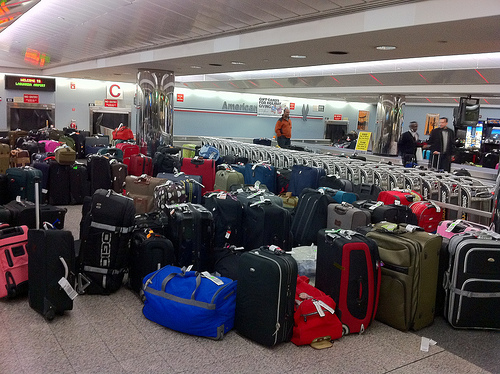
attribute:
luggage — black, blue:
[137, 260, 241, 342]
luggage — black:
[235, 240, 299, 348]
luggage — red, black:
[313, 225, 385, 344]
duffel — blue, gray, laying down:
[139, 259, 241, 342]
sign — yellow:
[353, 130, 376, 158]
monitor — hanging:
[450, 96, 486, 132]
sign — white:
[105, 81, 126, 102]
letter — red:
[109, 84, 121, 99]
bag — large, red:
[284, 271, 345, 353]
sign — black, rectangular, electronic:
[4, 73, 58, 94]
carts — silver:
[197, 134, 500, 233]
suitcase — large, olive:
[364, 218, 445, 337]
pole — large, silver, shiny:
[133, 65, 177, 161]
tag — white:
[199, 267, 225, 290]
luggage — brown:
[122, 171, 169, 218]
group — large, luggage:
[1, 123, 498, 353]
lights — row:
[179, 25, 401, 76]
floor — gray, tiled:
[2, 158, 500, 373]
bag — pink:
[435, 218, 490, 249]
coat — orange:
[275, 116, 296, 142]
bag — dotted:
[151, 176, 194, 218]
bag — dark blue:
[285, 163, 326, 197]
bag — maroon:
[127, 148, 157, 177]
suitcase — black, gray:
[442, 225, 499, 333]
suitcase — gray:
[325, 199, 376, 241]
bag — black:
[125, 224, 179, 293]